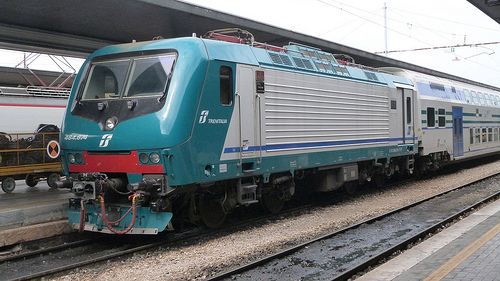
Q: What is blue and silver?
A: The train.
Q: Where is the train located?
A: On the tracks.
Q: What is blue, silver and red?
A: The passenger train.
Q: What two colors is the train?
A: Blue and white.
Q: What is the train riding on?
A: Train tracks.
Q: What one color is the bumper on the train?
A: Red.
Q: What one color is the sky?
A: White.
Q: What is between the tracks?
A: Gravel.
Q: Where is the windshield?
A: On the front of the train.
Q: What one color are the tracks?
A: Black.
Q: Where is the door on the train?
A: On the side.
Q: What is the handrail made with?
A: Metal.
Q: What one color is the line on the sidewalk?
A: Orange.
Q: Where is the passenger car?
A: Behind the engine.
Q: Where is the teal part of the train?
A: On engine.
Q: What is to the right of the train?
A: Platform.